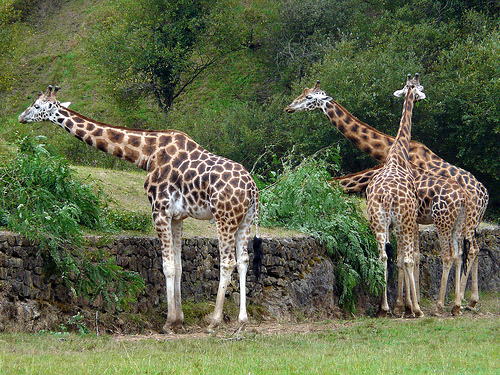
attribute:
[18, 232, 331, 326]
wall — stone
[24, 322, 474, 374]
grass — green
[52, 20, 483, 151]
trees — grouped, beautiful, green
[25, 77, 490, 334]
giraffes — grouped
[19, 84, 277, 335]
giraffe — looking, tall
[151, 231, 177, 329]
leg — long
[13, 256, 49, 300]
stones — hard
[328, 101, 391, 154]
neck — long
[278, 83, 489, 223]
giraffe — eating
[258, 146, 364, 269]
bush — green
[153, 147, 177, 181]
spot — brown, large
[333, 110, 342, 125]
spot — large, brown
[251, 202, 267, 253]
tail — black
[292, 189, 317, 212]
leaves — green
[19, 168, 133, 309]
foliage — green